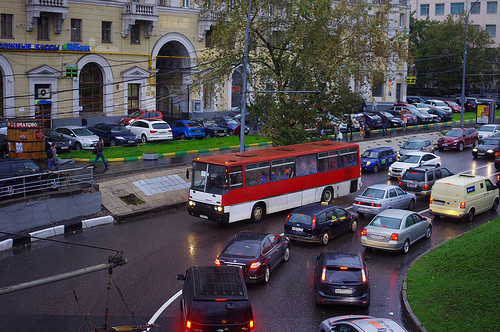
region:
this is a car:
[172, 251, 250, 329]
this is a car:
[217, 219, 287, 278]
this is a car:
[312, 308, 400, 329]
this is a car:
[302, 235, 378, 307]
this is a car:
[290, 195, 351, 247]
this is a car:
[367, 195, 424, 270]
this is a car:
[343, 165, 403, 225]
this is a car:
[388, 135, 443, 202]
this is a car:
[132, 111, 170, 141]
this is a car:
[37, 90, 107, 166]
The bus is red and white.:
[184, 137, 365, 227]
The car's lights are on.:
[173, 261, 260, 330]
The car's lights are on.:
[211, 223, 295, 292]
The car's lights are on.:
[277, 199, 366, 253]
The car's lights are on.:
[308, 240, 375, 309]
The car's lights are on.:
[356, 199, 436, 255]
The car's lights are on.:
[469, 129, 499, 159]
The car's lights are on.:
[385, 149, 444, 181]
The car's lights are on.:
[427, 167, 499, 225]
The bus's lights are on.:
[176, 135, 363, 230]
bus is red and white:
[179, 135, 379, 227]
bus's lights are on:
[183, 198, 238, 223]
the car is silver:
[356, 204, 442, 254]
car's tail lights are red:
[344, 223, 416, 248]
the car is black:
[306, 248, 387, 317]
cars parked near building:
[1, 96, 474, 136]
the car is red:
[112, 106, 161, 123]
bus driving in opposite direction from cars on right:
[128, 116, 496, 329]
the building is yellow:
[0, 1, 418, 124]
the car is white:
[118, 106, 179, 142]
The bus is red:
[185, 138, 369, 243]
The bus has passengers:
[203, 130, 364, 227]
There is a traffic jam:
[204, 155, 493, 329]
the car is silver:
[373, 213, 426, 253]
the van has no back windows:
[430, 176, 485, 212]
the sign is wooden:
[0, 113, 54, 190]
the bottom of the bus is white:
[203, 175, 361, 227]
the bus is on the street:
[186, 143, 398, 256]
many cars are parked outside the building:
[14, 98, 452, 199]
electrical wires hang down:
[1, 52, 256, 177]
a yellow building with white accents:
[2, 2, 407, 124]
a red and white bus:
[176, 139, 368, 224]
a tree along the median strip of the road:
[188, 5, 420, 147]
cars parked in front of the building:
[43, 90, 474, 154]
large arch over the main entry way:
[143, 22, 206, 122]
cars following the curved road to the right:
[173, 174, 489, 326]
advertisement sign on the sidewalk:
[472, 94, 496, 127]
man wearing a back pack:
[39, 137, 64, 175]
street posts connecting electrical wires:
[7, 39, 492, 141]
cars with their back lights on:
[167, 227, 292, 331]